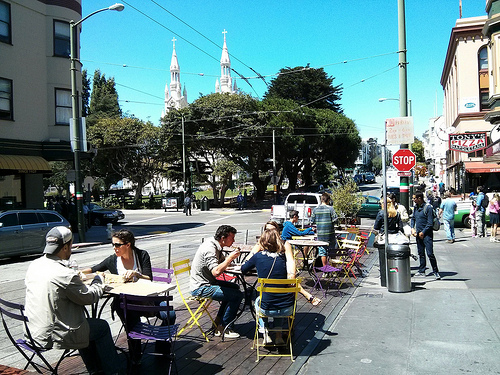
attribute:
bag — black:
[385, 251, 417, 261]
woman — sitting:
[89, 229, 158, 278]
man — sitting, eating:
[190, 227, 244, 340]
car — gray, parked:
[0, 210, 73, 256]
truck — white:
[271, 192, 333, 227]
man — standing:
[410, 192, 441, 278]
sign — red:
[392, 151, 416, 170]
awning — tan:
[464, 161, 499, 177]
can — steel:
[386, 239, 414, 295]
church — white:
[164, 35, 185, 118]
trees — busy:
[164, 92, 257, 211]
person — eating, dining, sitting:
[240, 230, 298, 369]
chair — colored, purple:
[318, 240, 362, 291]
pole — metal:
[69, 26, 82, 248]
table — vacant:
[290, 237, 333, 293]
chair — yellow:
[254, 276, 295, 361]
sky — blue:
[90, 2, 453, 117]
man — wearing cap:
[21, 224, 111, 374]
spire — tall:
[159, 34, 195, 119]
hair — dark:
[212, 226, 240, 237]